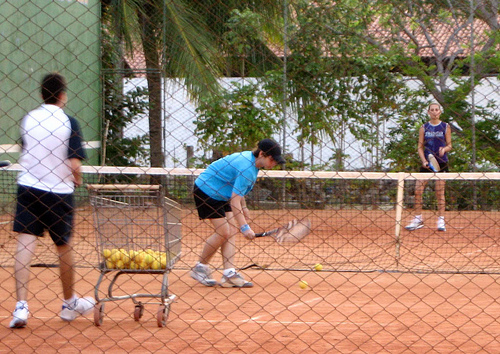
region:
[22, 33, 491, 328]
tennis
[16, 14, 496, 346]
a tennis court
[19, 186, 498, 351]
the tennis court has a reddish tan surface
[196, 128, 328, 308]
a man holding a racket reaches down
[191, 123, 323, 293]
the person reaching down is wearing a blue shirt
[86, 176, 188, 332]
a shopping cart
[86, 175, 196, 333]
a shopping cart full of tennis balls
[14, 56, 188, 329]
a person in white and black walks past the shopping cart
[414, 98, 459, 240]
a woman waits on the far side of the court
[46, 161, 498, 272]
a low net separates the sides of the tennis court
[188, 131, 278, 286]
this is a boy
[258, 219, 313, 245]
this is a racket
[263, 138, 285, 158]
this is a cap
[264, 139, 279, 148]
the cap is black in color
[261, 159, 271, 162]
the boy is light skinned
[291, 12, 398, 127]
this is a tree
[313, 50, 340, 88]
the tree has green leaves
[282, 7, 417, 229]
this is a fence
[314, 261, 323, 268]
this is a ball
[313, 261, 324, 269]
the ball is yellow in color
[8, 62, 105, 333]
a person is standing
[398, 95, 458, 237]
a person is standing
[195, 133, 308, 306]
a person is standing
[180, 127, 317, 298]
a person holding a tennis racket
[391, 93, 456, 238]
a person holding a tennis racket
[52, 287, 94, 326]
a white shoe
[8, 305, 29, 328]
a white shoe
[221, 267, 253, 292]
a white shoe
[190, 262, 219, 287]
a white shoe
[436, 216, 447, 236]
a white shoe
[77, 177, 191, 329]
shopping cart with tennis balls in it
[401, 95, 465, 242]
young woman playing tennis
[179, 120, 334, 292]
a man playing tennis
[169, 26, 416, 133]
greenery along a fence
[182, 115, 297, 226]
man with blue shirt on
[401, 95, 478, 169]
young woman wearing purple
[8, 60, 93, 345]
man wearing shorts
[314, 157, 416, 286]
tennis net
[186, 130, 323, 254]
man holding a tennis raquet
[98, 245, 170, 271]
many yellow tennis balls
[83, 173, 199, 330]
Shopping cart to hold tennis balls.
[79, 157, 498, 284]
Tennis net.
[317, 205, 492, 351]
Clay tennis court surface.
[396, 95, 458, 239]
Tennis player practicing techniques.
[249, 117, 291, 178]
Baseball hat for head protection.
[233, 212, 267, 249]
Sweat band to prevent wet hands.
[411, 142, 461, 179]
Tennis racket for hitting tennis balls.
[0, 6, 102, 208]
Green barrier to prevent balls from flying out of play area.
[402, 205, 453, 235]
Tennis shoes for mobility.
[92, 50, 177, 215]
Gate to enter court area.